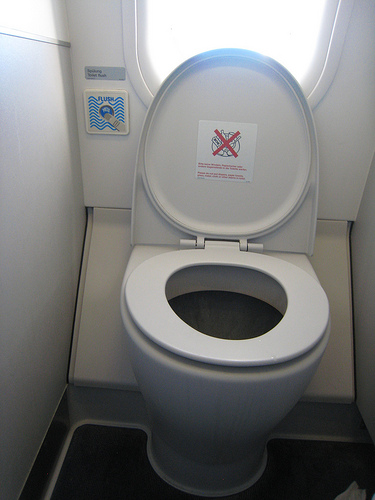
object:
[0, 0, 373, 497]
toilet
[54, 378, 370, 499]
board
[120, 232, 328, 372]
seat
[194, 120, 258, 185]
sticker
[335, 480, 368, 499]
paper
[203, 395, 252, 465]
stains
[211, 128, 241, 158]
letters